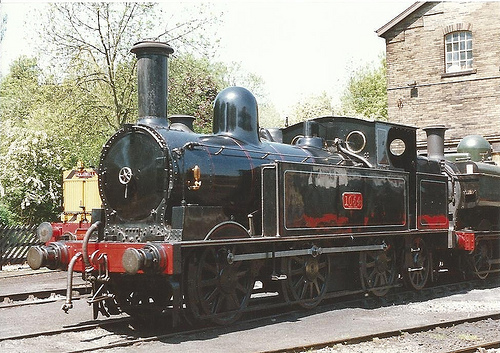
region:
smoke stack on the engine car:
[125, 35, 186, 118]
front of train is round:
[101, 121, 163, 231]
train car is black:
[166, 70, 420, 247]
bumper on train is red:
[56, 240, 160, 276]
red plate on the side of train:
[341, 188, 379, 210]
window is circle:
[338, 129, 363, 152]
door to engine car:
[397, 116, 433, 240]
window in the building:
[440, 31, 482, 80]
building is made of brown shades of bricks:
[437, 42, 486, 123]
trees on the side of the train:
[83, 44, 200, 117]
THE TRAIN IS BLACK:
[16, 33, 498, 335]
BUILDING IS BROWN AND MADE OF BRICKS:
[375, 0, 497, 170]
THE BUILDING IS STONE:
[372, 3, 497, 172]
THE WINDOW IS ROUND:
[336, 125, 421, 174]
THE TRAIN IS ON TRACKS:
[1, 271, 495, 351]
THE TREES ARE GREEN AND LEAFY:
[2, 2, 415, 213]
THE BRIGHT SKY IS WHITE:
[2, 2, 497, 163]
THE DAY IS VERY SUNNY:
[2, 0, 499, 350]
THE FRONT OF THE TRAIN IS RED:
[23, 216, 179, 291]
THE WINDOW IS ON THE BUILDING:
[438, 24, 482, 75]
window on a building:
[415, 26, 485, 104]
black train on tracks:
[57, 61, 461, 330]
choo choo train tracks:
[12, 265, 165, 350]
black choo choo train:
[23, 93, 478, 318]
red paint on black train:
[44, 199, 247, 300]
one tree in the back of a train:
[48, 21, 179, 144]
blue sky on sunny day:
[230, 45, 360, 98]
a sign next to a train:
[41, 165, 98, 236]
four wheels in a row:
[142, 277, 433, 337]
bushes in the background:
[20, 129, 85, 233]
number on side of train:
[341, 190, 366, 212]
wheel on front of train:
[118, 168, 130, 185]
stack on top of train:
[130, 37, 174, 123]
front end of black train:
[25, 220, 175, 280]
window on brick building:
[438, 23, 479, 80]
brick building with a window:
[374, 0, 499, 145]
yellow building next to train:
[60, 163, 99, 222]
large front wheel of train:
[194, 230, 264, 327]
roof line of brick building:
[370, 0, 436, 39]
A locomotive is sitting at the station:
[25, 30, 480, 325]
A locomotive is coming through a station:
[48, 23, 492, 323]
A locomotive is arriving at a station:
[20, 30, 480, 320]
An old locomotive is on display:
[20, 25, 480, 336]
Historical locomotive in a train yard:
[20, 16, 480, 326]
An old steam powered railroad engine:
[20, 20, 480, 330]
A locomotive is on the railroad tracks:
[17, 30, 472, 335]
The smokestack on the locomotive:
[130, 40, 175, 107]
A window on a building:
[438, 23, 474, 75]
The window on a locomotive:
[344, 130, 366, 154]